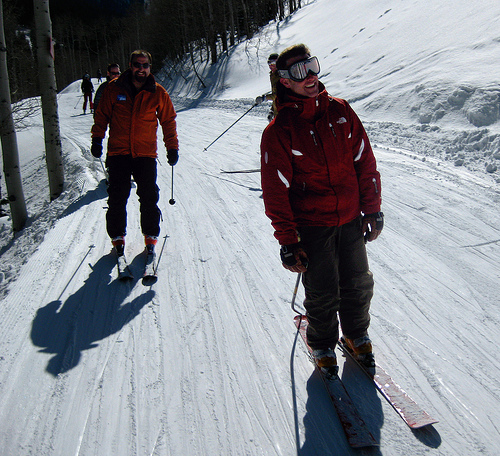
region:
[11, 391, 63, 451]
Snow covering the ground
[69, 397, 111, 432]
Snow covering the ground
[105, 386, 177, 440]
Snow covering the ground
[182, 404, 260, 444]
Snow covering the ground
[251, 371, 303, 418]
Snow covering the ground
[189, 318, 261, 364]
Snow covering the ground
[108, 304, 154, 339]
Snow covering the ground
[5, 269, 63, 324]
Snow covering the ground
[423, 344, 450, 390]
Snow covering the ground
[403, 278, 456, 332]
Snow covering the ground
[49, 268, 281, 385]
ground covered in snow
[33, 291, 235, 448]
ground covered in white snow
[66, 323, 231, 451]
snow covering the ground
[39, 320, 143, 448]
white snow covering the ground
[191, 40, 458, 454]
men on skies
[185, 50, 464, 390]
men standing on skie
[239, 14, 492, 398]
men skiing on the snow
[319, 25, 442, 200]
a hill covered in snow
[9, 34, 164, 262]
trees in the snow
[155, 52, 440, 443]
a man wearing a red jacket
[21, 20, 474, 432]
group of people cross country skiing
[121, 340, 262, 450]
ski marks in the snow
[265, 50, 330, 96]
woman with goggles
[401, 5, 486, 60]
bank of fresh snow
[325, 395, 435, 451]
tips of red snow skis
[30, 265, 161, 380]
shadow of a skier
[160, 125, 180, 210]
arm and ski pole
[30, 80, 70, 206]
trunk of tree at the edge of the trail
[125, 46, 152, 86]
man with goatee and sunglasses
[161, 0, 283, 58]
trees in the snow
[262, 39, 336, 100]
head of a person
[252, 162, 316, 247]
leg of a person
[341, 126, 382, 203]
leg of a person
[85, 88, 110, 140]
leg of a person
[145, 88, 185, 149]
leg of a person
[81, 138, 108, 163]
hand of a person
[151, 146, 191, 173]
hand of a person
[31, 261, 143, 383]
shadow of a person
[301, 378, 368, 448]
shadow of a person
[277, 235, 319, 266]
hand of a person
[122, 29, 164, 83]
head of a person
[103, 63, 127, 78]
head of a person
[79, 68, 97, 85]
head of a person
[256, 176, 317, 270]
arm of a person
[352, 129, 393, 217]
arm of a person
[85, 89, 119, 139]
arm of a person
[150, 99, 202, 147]
arm of a person